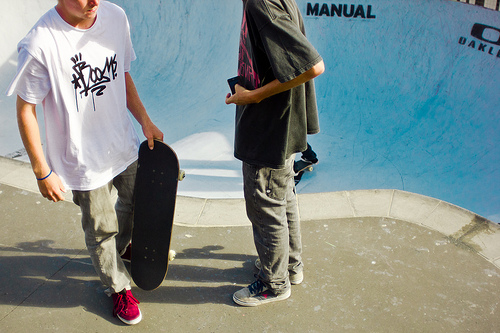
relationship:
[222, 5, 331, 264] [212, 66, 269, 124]
boy with phone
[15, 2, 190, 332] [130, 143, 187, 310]
man with skateboard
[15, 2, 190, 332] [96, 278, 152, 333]
man wearing shoe